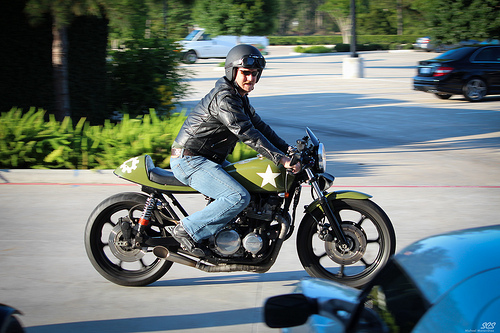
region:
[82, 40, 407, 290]
Man riding a motorcycle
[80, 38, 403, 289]
Man riding a green, white and black motorcycle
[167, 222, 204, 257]
Man is wearing shoes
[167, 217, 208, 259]
Man is wearing black shoes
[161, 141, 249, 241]
Man is wearing jeans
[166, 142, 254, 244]
Man is wearing blue jeans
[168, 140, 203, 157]
Man is wearing a belt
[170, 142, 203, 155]
Man is wearing a brown belt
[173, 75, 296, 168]
Man is wearing a jacket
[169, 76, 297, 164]
Man is wearing a black jacket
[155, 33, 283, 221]
this is a motorist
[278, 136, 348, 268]
this is a motorbike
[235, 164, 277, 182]
the motorbike is green in color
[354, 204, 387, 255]
this is the wheel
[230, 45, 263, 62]
he is wearing helmet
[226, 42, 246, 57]
the helmet is black in color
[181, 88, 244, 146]
the jacket is black in color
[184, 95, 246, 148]
the jacket is leather like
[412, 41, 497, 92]
this is a car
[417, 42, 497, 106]
the car is parked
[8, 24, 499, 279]
This man is on a motorcycle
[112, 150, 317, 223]
The motorcycle is green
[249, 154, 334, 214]
This is a star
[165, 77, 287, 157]
The man has a leather jacket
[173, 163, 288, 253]
The man is wearing blue jeans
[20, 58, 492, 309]
This is in a parking lot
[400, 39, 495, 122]
This is a car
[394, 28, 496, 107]
This car is black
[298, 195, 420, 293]
This tire is black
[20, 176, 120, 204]
There is a red line on the ground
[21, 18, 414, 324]
picture taken outdoors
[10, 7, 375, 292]
picture taken during the day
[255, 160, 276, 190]
a white star onthe motorcycle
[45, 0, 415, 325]
a man riding a motorcycle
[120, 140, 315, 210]
the motorcycle is green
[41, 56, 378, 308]
the man is riding on the street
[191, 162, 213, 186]
the man is wearing blue jeans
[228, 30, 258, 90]
the man is wearing a helmet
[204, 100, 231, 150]
the man wears a leather jacket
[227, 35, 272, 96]
the man is looking to the right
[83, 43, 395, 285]
the man on the motorcycle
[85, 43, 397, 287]
the man riding on the motorcycle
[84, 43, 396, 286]
the man sitting on the motorcycle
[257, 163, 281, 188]
the white star on the motorcycle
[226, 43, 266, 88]
the helmet on the man's head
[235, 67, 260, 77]
the sunglasses on the man's face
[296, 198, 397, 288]
the front tire on the motorcycle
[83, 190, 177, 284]
the back tire on the motorcycle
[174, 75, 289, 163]
the man's black jacket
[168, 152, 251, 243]
the denim jeans on the man